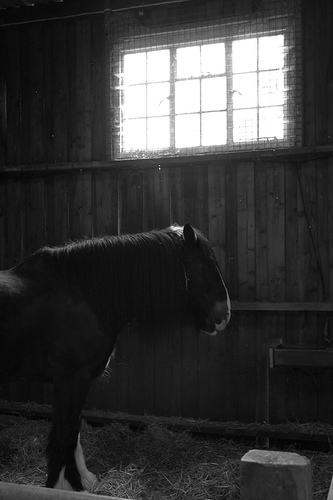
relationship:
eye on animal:
[202, 253, 215, 267] [10, 220, 241, 486]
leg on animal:
[38, 378, 96, 486] [10, 220, 241, 486]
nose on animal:
[208, 304, 227, 332] [10, 220, 241, 486]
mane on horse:
[79, 242, 195, 284] [22, 223, 271, 416]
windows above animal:
[116, 30, 287, 155] [10, 220, 241, 486]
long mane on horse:
[22, 229, 189, 356] [0, 221, 230, 374]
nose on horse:
[208, 304, 227, 332] [0, 221, 230, 374]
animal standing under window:
[10, 220, 241, 486] [109, 14, 297, 162]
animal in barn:
[10, 220, 241, 486] [1, 11, 329, 494]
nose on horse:
[208, 304, 227, 332] [0, 217, 229, 403]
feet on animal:
[45, 458, 98, 490] [10, 220, 241, 486]